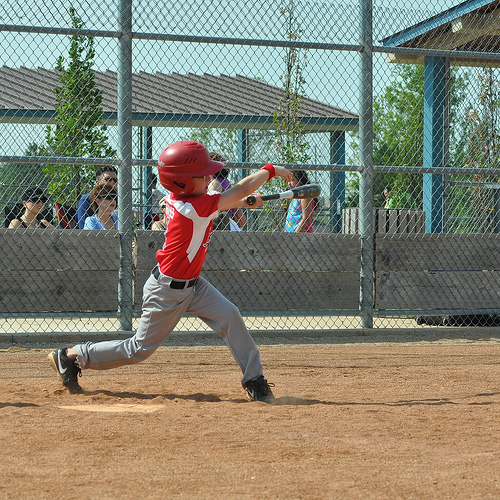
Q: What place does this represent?
A: It represents the field.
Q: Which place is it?
A: It is a field.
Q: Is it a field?
A: Yes, it is a field.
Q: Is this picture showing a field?
A: Yes, it is showing a field.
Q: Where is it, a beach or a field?
A: It is a field.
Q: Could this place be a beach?
A: No, it is a field.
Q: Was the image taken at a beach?
A: No, the picture was taken in a field.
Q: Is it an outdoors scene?
A: Yes, it is outdoors.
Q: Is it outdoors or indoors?
A: It is outdoors.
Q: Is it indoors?
A: No, it is outdoors.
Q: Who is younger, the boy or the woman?
A: The boy is younger than the woman.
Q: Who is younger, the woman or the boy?
A: The boy is younger than the woman.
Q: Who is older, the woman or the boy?
A: The woman is older than the boy.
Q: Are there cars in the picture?
A: No, there are no cars.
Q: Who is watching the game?
A: The people are watching the game.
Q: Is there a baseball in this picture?
A: Yes, there is a baseball.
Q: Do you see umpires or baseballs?
A: Yes, there is a baseball.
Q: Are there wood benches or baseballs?
A: Yes, there is a wood baseball.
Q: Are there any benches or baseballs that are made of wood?
A: Yes, the baseball is made of wood.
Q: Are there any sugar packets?
A: No, there are no sugar packets.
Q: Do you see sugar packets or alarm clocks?
A: No, there are no sugar packets or alarm clocks.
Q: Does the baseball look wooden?
A: Yes, the baseball is wooden.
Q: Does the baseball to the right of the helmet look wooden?
A: Yes, the baseball is wooden.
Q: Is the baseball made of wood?
A: Yes, the baseball is made of wood.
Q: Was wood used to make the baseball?
A: Yes, the baseball is made of wood.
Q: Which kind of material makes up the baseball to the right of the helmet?
A: The baseball is made of wood.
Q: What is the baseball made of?
A: The baseball is made of wood.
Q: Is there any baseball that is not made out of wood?
A: No, there is a baseball but it is made of wood.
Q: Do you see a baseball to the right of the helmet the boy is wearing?
A: Yes, there is a baseball to the right of the helmet.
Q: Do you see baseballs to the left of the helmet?
A: No, the baseball is to the right of the helmet.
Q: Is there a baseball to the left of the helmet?
A: No, the baseball is to the right of the helmet.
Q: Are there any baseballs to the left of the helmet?
A: No, the baseball is to the right of the helmet.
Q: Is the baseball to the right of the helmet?
A: Yes, the baseball is to the right of the helmet.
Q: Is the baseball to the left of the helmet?
A: No, the baseball is to the right of the helmet.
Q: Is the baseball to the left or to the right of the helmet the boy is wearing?
A: The baseball is to the right of the helmet.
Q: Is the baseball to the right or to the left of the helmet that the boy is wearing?
A: The baseball is to the right of the helmet.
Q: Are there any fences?
A: Yes, there is a fence.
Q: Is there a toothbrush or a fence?
A: Yes, there is a fence.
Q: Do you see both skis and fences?
A: No, there is a fence but no skis.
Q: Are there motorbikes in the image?
A: No, there are no motorbikes.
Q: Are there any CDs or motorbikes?
A: No, there are no motorbikes or cds.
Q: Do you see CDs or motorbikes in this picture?
A: No, there are no motorbikes or cds.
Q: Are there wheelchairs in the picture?
A: No, there are no wheelchairs.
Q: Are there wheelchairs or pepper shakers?
A: No, there are no wheelchairs or pepper shakers.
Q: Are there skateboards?
A: No, there are no skateboards.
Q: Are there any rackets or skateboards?
A: No, there are no skateboards or rackets.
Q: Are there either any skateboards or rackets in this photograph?
A: No, there are no skateboards or rackets.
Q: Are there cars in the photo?
A: No, there are no cars.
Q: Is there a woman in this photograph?
A: Yes, there is a woman.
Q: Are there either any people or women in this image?
A: Yes, there is a woman.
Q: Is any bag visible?
A: No, there are no bags.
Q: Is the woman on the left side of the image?
A: Yes, the woman is on the left of the image.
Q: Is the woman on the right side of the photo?
A: No, the woman is on the left of the image.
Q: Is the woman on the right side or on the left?
A: The woman is on the left of the image.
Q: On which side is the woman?
A: The woman is on the left of the image.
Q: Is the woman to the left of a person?
A: Yes, the woman is to the left of a person.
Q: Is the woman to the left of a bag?
A: No, the woman is to the left of a person.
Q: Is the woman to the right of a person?
A: No, the woman is to the left of a person.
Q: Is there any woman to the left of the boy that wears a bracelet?
A: Yes, there is a woman to the left of the boy.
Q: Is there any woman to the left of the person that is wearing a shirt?
A: Yes, there is a woman to the left of the boy.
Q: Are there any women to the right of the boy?
A: No, the woman is to the left of the boy.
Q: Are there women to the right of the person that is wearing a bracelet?
A: No, the woman is to the left of the boy.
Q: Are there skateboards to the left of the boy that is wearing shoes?
A: No, there is a woman to the left of the boy.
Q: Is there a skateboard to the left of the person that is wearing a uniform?
A: No, there is a woman to the left of the boy.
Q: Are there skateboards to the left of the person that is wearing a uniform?
A: No, there is a woman to the left of the boy.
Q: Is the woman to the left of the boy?
A: Yes, the woman is to the left of the boy.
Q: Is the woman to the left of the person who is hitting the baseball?
A: Yes, the woman is to the left of the boy.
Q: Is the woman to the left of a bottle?
A: No, the woman is to the left of the boy.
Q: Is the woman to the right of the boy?
A: No, the woman is to the left of the boy.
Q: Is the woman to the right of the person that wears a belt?
A: No, the woman is to the left of the boy.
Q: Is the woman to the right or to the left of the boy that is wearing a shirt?
A: The woman is to the left of the boy.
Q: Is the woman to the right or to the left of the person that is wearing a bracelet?
A: The woman is to the left of the boy.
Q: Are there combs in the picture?
A: No, there are no combs.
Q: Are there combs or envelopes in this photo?
A: No, there are no combs or envelopes.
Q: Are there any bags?
A: No, there are no bags.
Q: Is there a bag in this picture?
A: No, there are no bags.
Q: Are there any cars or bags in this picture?
A: No, there are no bags or cars.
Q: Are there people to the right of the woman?
A: Yes, there is a person to the right of the woman.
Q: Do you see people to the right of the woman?
A: Yes, there is a person to the right of the woman.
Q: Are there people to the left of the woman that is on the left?
A: No, the person is to the right of the woman.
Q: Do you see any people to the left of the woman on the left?
A: No, the person is to the right of the woman.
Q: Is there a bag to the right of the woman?
A: No, there is a person to the right of the woman.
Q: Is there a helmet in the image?
A: Yes, there is a helmet.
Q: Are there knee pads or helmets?
A: Yes, there is a helmet.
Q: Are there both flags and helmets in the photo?
A: No, there is a helmet but no flags.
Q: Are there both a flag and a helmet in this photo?
A: No, there is a helmet but no flags.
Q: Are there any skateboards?
A: No, there are no skateboards.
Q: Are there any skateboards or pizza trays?
A: No, there are no skateboards or pizza trays.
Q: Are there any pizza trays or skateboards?
A: No, there are no skateboards or pizza trays.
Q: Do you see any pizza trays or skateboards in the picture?
A: No, there are no skateboards or pizza trays.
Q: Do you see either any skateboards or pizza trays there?
A: No, there are no skateboards or pizza trays.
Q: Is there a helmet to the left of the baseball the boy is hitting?
A: Yes, there is a helmet to the left of the baseball.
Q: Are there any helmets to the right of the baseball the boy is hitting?
A: No, the helmet is to the left of the baseball.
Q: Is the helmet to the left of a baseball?
A: Yes, the helmet is to the left of a baseball.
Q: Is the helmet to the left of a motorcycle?
A: No, the helmet is to the left of a baseball.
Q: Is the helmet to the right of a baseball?
A: No, the helmet is to the left of a baseball.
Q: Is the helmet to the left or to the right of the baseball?
A: The helmet is to the left of the baseball.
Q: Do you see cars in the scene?
A: No, there are no cars.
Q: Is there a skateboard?
A: No, there are no skateboards.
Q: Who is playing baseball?
A: The boy is playing baseball.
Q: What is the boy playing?
A: The boy is playing baseball.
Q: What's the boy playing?
A: The boy is playing baseball.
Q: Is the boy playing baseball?
A: Yes, the boy is playing baseball.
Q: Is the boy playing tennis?
A: No, the boy is playing baseball.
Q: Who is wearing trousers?
A: The boy is wearing trousers.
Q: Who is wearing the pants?
A: The boy is wearing trousers.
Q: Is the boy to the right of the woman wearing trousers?
A: Yes, the boy is wearing trousers.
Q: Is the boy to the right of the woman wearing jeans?
A: No, the boy is wearing trousers.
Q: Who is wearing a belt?
A: The boy is wearing a belt.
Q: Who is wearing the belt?
A: The boy is wearing a belt.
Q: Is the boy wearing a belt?
A: Yes, the boy is wearing a belt.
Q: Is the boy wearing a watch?
A: No, the boy is wearing a belt.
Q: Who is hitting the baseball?
A: The boy is hitting the baseball.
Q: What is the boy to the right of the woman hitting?
A: The boy is hitting the baseball.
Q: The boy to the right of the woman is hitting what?
A: The boy is hitting the baseball.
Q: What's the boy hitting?
A: The boy is hitting the baseball.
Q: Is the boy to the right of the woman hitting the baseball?
A: Yes, the boy is hitting the baseball.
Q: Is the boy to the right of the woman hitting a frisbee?
A: No, the boy is hitting the baseball.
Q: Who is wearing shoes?
A: The boy is wearing shoes.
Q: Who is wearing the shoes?
A: The boy is wearing shoes.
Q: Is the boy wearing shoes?
A: Yes, the boy is wearing shoes.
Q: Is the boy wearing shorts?
A: No, the boy is wearing shoes.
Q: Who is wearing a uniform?
A: The boy is wearing a uniform.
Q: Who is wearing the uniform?
A: The boy is wearing a uniform.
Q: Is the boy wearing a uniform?
A: Yes, the boy is wearing a uniform.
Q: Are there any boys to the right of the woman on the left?
A: Yes, there is a boy to the right of the woman.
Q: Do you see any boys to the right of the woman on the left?
A: Yes, there is a boy to the right of the woman.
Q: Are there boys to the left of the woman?
A: No, the boy is to the right of the woman.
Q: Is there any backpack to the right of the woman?
A: No, there is a boy to the right of the woman.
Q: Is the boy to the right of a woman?
A: Yes, the boy is to the right of a woman.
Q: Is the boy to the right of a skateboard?
A: No, the boy is to the right of a woman.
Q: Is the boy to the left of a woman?
A: No, the boy is to the right of a woman.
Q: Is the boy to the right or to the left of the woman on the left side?
A: The boy is to the right of the woman.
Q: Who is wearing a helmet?
A: The boy is wearing a helmet.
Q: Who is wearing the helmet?
A: The boy is wearing a helmet.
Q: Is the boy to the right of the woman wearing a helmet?
A: Yes, the boy is wearing a helmet.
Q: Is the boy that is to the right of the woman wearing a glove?
A: No, the boy is wearing a helmet.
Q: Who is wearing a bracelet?
A: The boy is wearing a bracelet.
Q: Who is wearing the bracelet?
A: The boy is wearing a bracelet.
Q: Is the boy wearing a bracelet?
A: Yes, the boy is wearing a bracelet.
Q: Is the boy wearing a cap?
A: No, the boy is wearing a bracelet.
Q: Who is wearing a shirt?
A: The boy is wearing a shirt.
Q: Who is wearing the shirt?
A: The boy is wearing a shirt.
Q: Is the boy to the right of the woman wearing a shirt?
A: Yes, the boy is wearing a shirt.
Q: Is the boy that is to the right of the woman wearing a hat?
A: No, the boy is wearing a shirt.